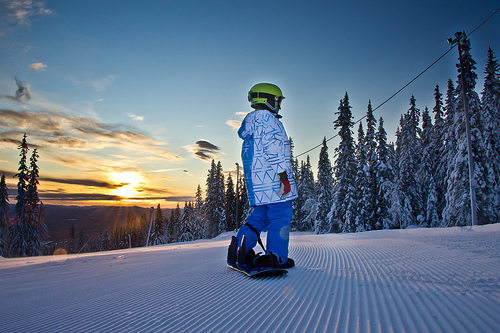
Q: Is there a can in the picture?
A: No, there are no cans.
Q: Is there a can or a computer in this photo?
A: No, there are no cans or computers.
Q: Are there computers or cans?
A: No, there are no cans or computers.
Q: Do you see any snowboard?
A: Yes, there is a snowboard.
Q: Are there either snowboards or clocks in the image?
A: Yes, there is a snowboard.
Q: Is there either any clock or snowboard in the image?
A: Yes, there is a snowboard.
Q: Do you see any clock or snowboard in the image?
A: Yes, there is a snowboard.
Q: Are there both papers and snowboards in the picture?
A: No, there is a snowboard but no papers.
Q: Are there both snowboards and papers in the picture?
A: No, there is a snowboard but no papers.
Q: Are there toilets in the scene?
A: No, there are no toilets.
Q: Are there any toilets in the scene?
A: No, there are no toilets.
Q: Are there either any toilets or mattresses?
A: No, there are no toilets or mattresses.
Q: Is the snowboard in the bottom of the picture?
A: Yes, the snowboard is in the bottom of the image.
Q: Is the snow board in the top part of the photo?
A: No, the snow board is in the bottom of the image.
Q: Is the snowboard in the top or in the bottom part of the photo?
A: The snowboard is in the bottom of the image.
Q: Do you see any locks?
A: No, there are no locks.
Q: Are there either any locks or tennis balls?
A: No, there are no locks or tennis balls.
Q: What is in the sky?
A: The sun is in the sky.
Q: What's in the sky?
A: The sun is in the sky.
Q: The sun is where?
A: The sun is in the sky.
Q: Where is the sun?
A: The sun is in the sky.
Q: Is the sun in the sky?
A: Yes, the sun is in the sky.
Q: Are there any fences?
A: No, there are no fences.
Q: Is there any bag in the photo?
A: No, there are no bags.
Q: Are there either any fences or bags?
A: No, there are no bags or fences.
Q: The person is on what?
A: The person is on the snowboard.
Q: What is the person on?
A: The person is on the snowboard.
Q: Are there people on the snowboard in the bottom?
A: Yes, there is a person on the snowboard.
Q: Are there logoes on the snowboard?
A: No, there is a person on the snowboard.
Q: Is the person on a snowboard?
A: Yes, the person is on a snowboard.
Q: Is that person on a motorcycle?
A: No, the person is on a snowboard.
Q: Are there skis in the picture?
A: No, there are no skis.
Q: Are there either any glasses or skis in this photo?
A: No, there are no skis or glasses.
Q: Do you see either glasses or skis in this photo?
A: No, there are no skis or glasses.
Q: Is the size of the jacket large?
A: Yes, the jacket is large.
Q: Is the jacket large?
A: Yes, the jacket is large.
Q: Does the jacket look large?
A: Yes, the jacket is large.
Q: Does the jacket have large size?
A: Yes, the jacket is large.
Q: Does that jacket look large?
A: Yes, the jacket is large.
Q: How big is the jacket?
A: The jacket is large.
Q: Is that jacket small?
A: No, the jacket is large.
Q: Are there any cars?
A: No, there are no cars.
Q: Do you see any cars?
A: No, there are no cars.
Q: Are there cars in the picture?
A: No, there are no cars.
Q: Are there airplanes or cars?
A: No, there are no cars or airplanes.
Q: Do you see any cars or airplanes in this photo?
A: No, there are no cars or airplanes.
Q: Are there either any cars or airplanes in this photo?
A: No, there are no cars or airplanes.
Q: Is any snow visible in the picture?
A: Yes, there is snow.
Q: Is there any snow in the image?
A: Yes, there is snow.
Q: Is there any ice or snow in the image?
A: Yes, there is snow.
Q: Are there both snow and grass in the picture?
A: No, there is snow but no grass.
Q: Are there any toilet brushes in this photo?
A: No, there are no toilet brushes.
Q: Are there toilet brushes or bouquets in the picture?
A: No, there are no toilet brushes or bouquets.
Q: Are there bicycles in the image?
A: No, there are no bicycles.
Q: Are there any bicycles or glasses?
A: No, there are no bicycles or glasses.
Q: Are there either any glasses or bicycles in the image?
A: No, there are no bicycles or glasses.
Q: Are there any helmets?
A: Yes, there is a helmet.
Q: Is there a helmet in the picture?
A: Yes, there is a helmet.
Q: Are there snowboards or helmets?
A: Yes, there is a helmet.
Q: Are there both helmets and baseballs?
A: No, there is a helmet but no baseballs.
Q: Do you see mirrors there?
A: No, there are no mirrors.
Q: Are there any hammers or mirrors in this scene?
A: No, there are no mirrors or hammers.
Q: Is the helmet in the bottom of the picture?
A: No, the helmet is in the top of the image.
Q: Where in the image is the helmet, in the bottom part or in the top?
A: The helmet is in the top of the image.